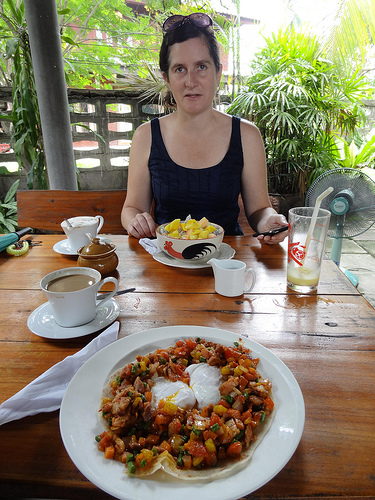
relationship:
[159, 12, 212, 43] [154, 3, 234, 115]
glasses on top of head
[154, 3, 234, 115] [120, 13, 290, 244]
head attached to person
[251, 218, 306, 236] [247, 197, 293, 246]
cell phone in hand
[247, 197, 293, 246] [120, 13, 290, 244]
hand attached to person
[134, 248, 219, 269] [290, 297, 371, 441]
plate on top of table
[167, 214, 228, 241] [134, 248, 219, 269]
food on top of plate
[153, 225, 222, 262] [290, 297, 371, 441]
bowl on top of table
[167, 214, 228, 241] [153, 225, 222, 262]
food on top of bowl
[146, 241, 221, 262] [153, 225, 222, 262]
chicken on side of bowl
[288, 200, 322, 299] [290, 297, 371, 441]
glass on top of table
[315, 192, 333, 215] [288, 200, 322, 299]
straw on top of glass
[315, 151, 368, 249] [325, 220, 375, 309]
fan on top of floor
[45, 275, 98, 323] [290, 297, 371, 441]
coffee on top of table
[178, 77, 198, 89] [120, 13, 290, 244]
nose attached to person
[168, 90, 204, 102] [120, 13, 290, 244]
mouth attached to person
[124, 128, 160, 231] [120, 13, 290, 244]
arm attached to person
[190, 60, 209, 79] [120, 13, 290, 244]
eye attached to person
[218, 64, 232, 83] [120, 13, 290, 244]
ear attached to person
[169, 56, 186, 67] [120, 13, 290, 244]
eyebrow attached to person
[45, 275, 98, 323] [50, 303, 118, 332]
coffee inside of cup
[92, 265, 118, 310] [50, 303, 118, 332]
handle attached to cup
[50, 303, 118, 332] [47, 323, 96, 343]
cup on top of saucer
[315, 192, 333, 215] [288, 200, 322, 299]
straw inside of glass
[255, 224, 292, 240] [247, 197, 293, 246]
phone inside of hand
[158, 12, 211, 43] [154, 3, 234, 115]
glasses attached to head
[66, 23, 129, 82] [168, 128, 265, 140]
plants behind person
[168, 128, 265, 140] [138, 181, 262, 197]
person wearing shirt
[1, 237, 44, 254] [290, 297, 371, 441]
keys on top of table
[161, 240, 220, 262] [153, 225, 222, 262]
chicken on side of bowl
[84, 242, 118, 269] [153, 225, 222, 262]
sugar inside of bowl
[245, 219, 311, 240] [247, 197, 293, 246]
cell phone inside of hand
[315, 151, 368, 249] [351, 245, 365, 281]
fan on top of floor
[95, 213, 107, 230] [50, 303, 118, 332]
foam on top of cup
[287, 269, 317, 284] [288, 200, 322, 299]
juice inside of glass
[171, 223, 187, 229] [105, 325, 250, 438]
eggs on top of tortilla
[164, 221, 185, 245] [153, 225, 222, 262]
fruit inside of bowl